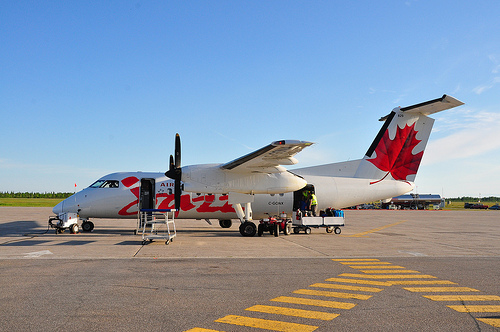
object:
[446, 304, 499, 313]
line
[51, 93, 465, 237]
plane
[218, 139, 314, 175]
wing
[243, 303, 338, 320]
line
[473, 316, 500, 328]
line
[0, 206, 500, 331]
pavement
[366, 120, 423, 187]
design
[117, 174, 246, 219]
design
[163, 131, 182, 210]
propeller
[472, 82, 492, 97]
clouds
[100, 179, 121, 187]
cockpit window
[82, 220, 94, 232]
tires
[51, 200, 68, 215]
nose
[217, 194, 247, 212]
letters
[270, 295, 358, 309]
line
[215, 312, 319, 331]
line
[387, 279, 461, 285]
line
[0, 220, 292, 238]
shadow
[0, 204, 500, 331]
ground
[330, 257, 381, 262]
signs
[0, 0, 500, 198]
sky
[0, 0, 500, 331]
background